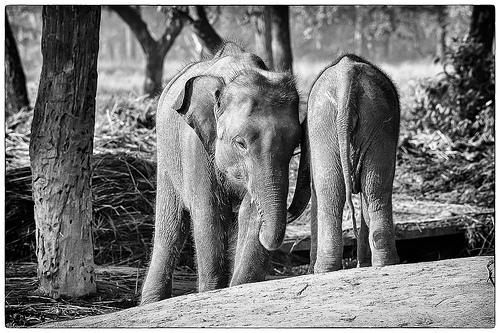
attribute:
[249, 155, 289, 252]
trunk — baby, elephant, curled under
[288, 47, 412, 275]
elephant — facing away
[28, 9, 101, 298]
tree — grey and white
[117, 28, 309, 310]
elephant — facing camera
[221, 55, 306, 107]
baby hair — fuzzy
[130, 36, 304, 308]
elephant — small, hairy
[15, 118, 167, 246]
straw — pile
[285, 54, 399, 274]
elephant — large, grey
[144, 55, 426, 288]
elephants — baby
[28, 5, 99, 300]
trunk — tree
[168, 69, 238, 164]
ear — curled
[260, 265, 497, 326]
hill — small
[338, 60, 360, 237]
tail — long, thin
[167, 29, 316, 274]
elephant — baby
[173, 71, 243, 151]
ear — elephant, folded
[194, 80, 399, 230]
elephants — standing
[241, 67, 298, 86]
hair — sticking out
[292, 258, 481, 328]
ground — dirt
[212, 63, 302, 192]
elephant head — baby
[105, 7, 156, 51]
branch — tree